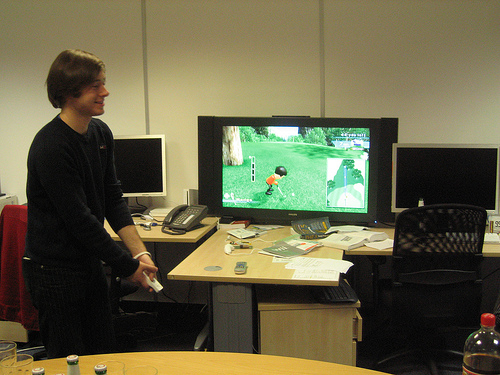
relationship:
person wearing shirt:
[20, 44, 160, 357] [27, 121, 132, 261]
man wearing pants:
[16, 42, 214, 372] [21, 254, 127, 356]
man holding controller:
[8, 41, 161, 343] [126, 264, 163, 293]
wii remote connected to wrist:
[131, 249, 164, 295] [129, 246, 151, 263]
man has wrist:
[20, 47, 160, 343] [129, 246, 151, 263]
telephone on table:
[159, 198, 210, 235] [103, 201, 220, 244]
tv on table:
[159, 83, 425, 256] [174, 202, 393, 300]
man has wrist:
[20, 47, 160, 343] [130, 243, 152, 270]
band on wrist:
[127, 247, 154, 258] [130, 243, 152, 270]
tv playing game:
[197, 117, 395, 216] [215, 128, 368, 213]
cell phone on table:
[232, 257, 252, 277] [166, 219, 499, 284]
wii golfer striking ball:
[263, 165, 286, 199] [290, 193, 295, 197]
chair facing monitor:
[365, 204, 494, 374] [392, 139, 496, 196]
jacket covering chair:
[1, 203, 51, 335] [347, 202, 499, 369]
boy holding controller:
[15, 41, 168, 360] [138, 266, 165, 295]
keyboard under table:
[316, 282, 357, 305] [103, 201, 220, 244]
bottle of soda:
[454, 305, 499, 370] [465, 354, 497, 372]